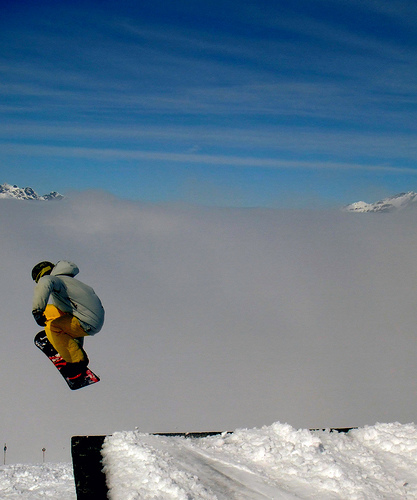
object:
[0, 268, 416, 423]
ramp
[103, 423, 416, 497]
snow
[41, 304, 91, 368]
pants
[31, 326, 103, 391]
snowboard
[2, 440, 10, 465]
sign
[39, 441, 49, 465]
sign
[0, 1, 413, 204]
sky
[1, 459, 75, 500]
snow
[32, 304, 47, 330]
gloves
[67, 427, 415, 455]
slope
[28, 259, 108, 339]
jacket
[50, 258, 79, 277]
hood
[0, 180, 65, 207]
mountain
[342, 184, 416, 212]
mountain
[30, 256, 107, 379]
guy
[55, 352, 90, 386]
boot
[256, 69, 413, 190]
clouds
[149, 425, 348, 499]
snowboard tracks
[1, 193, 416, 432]
fog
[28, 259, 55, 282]
safety helmet